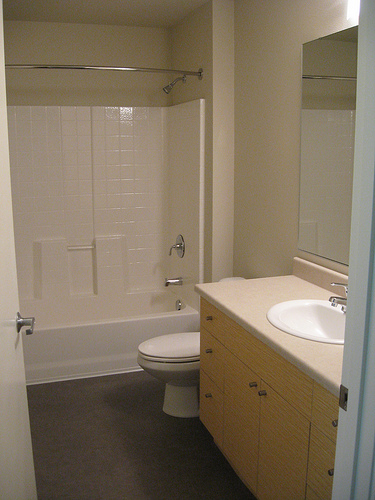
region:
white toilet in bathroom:
[123, 319, 217, 413]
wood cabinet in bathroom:
[195, 378, 215, 453]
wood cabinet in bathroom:
[191, 341, 227, 379]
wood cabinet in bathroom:
[198, 299, 229, 340]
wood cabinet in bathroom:
[221, 357, 257, 498]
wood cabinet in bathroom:
[263, 384, 312, 499]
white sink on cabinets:
[287, 290, 366, 342]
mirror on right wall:
[295, 50, 374, 239]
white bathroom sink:
[256, 286, 346, 352]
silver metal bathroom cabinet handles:
[238, 373, 268, 400]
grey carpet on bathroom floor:
[40, 380, 160, 490]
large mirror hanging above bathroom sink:
[297, 18, 358, 262]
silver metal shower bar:
[0, 60, 204, 75]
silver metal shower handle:
[150, 228, 195, 266]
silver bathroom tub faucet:
[160, 270, 184, 294]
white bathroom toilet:
[130, 326, 203, 420]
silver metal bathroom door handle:
[12, 306, 38, 346]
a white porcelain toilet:
[136, 331, 198, 418]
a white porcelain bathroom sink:
[266, 299, 344, 344]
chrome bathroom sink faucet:
[329, 280, 348, 313]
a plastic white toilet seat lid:
[137, 332, 200, 359]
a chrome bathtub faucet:
[161, 276, 181, 286]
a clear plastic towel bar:
[67, 244, 93, 250]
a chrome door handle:
[15, 312, 35, 336]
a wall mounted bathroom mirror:
[297, 23, 358, 269]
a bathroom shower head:
[161, 75, 187, 93]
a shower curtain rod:
[4, 62, 202, 82]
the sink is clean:
[269, 289, 356, 359]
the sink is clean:
[277, 286, 347, 352]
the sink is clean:
[256, 267, 351, 366]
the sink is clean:
[252, 281, 342, 365]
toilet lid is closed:
[112, 320, 225, 401]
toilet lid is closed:
[143, 332, 203, 389]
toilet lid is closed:
[126, 315, 233, 431]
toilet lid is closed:
[95, 306, 209, 429]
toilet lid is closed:
[107, 308, 228, 425]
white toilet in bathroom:
[136, 326, 204, 427]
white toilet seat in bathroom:
[145, 329, 204, 361]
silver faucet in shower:
[163, 237, 182, 255]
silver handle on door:
[16, 314, 37, 336]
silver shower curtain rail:
[2, 63, 209, 75]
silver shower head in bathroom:
[153, 74, 188, 101]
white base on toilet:
[135, 324, 200, 427]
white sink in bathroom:
[269, 296, 353, 353]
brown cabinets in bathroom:
[180, 309, 338, 498]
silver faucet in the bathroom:
[162, 272, 182, 288]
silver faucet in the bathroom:
[328, 292, 347, 307]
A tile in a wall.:
[115, 106, 127, 119]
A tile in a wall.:
[119, 116, 133, 133]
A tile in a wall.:
[121, 133, 132, 145]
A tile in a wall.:
[120, 150, 133, 160]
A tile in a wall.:
[122, 162, 137, 180]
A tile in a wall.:
[132, 174, 150, 191]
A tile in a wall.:
[119, 202, 132, 220]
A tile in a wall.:
[104, 205, 125, 220]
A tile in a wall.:
[62, 177, 76, 196]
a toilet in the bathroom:
[151, 323, 216, 409]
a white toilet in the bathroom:
[137, 321, 224, 421]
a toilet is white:
[153, 328, 211, 423]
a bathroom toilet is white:
[146, 323, 185, 406]